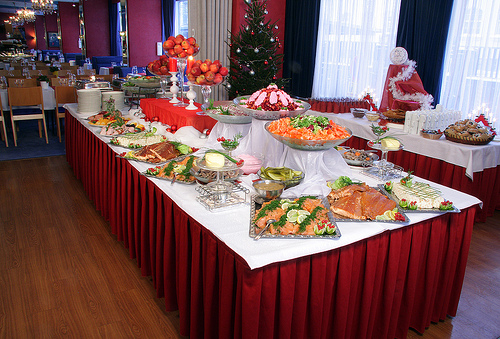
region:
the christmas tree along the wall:
[221, 0, 291, 99]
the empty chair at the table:
[5, 85, 48, 145]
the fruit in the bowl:
[184, 58, 227, 111]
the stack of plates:
[75, 88, 123, 114]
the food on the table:
[62, 34, 459, 240]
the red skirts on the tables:
[61, 92, 498, 336]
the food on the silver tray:
[253, 197, 332, 235]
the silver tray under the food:
[248, 192, 340, 241]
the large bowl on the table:
[263, 116, 353, 150]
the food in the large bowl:
[268, 115, 350, 146]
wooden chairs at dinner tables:
[3, 50, 125, 145]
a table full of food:
[64, 35, 482, 336]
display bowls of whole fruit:
[149, 35, 226, 107]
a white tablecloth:
[62, 94, 482, 267]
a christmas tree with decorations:
[229, 0, 284, 93]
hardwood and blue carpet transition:
[1, 129, 64, 166]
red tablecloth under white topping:
[64, 108, 476, 337]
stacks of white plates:
[78, 86, 124, 115]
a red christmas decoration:
[385, 46, 432, 112]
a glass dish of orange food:
[265, 111, 351, 151]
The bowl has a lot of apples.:
[185, 59, 226, 87]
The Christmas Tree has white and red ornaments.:
[225, 2, 283, 95]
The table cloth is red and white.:
[63, 102, 478, 338]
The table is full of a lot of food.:
[64, 102, 481, 337]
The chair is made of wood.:
[6, 87, 48, 145]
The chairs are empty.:
[0, 48, 149, 144]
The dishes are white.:
[77, 89, 124, 116]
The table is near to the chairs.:
[67, 102, 477, 338]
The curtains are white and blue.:
[282, 1, 498, 142]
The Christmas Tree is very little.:
[228, 0, 281, 92]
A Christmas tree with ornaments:
[224, 0, 292, 98]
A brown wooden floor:
[1, 155, 498, 336]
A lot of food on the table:
[86, 30, 464, 244]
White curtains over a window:
[312, 0, 400, 102]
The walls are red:
[33, 0, 283, 79]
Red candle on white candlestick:
[161, 51, 183, 111]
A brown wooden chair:
[4, 80, 52, 147]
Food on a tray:
[247, 192, 343, 243]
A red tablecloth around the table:
[61, 111, 477, 336]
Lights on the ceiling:
[4, 0, 58, 31]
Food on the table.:
[97, 35, 387, 284]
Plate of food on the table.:
[237, 171, 347, 263]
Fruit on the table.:
[141, 18, 313, 130]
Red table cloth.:
[195, 202, 354, 334]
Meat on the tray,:
[308, 147, 392, 225]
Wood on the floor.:
[35, 160, 145, 312]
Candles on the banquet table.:
[152, 49, 234, 129]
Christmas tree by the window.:
[227, 12, 340, 129]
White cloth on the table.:
[164, 120, 362, 248]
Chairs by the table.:
[20, 52, 132, 153]